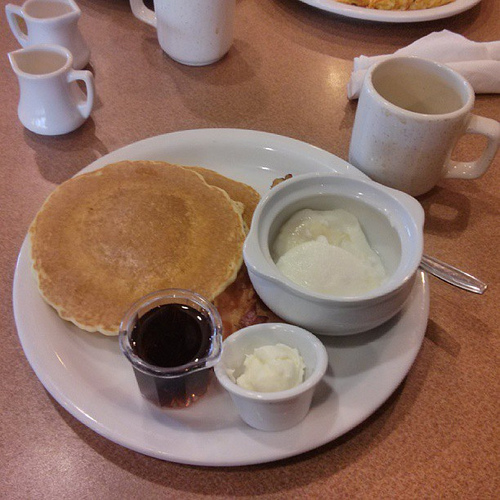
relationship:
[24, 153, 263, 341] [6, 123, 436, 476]
pancake on plate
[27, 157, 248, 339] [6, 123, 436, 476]
pancake lying on top of plate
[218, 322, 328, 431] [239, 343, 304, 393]
container with butter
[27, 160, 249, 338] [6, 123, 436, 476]
pancake on plate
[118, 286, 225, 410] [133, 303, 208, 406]
container for syrup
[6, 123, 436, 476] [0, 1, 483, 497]
plate on table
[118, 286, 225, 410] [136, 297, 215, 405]
container of syrup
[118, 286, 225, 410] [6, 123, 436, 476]
container on plate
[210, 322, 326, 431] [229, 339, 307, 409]
container of butter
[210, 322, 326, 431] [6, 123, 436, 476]
container on plate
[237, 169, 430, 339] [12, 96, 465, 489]
bowl on top of plate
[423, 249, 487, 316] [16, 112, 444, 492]
silverware on top of plate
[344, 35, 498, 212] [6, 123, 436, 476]
coffee mug next to plate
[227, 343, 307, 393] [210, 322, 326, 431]
butter in a container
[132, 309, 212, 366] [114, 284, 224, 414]
syrup in a cup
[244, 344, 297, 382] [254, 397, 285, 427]
butter in a bowl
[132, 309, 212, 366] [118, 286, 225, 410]
syrup in a container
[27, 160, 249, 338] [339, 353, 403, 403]
pancake are on a plate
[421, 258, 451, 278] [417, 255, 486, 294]
handle on a silverware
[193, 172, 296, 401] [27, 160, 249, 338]
bacon next to pancake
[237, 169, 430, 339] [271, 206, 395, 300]
bowl with butter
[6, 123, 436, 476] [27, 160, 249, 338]
plate with pancake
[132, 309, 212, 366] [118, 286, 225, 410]
syrup in container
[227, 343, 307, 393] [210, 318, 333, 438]
butter in container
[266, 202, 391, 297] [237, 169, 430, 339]
grits in bowl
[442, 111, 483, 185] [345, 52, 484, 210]
handle of coffee cup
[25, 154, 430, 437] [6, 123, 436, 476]
breakfast on plate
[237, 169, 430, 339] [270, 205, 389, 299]
bowl has egg whites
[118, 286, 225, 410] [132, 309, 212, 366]
container of syrup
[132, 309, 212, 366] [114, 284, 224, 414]
syrup in cup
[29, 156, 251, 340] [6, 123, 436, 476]
food on plate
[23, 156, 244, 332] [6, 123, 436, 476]
food on plate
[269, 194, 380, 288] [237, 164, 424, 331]
food on bowl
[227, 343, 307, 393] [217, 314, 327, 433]
butter in cup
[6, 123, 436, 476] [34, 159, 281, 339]
plate under food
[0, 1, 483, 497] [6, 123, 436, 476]
table under plate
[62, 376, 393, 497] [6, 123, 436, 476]
shadow from plate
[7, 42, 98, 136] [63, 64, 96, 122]
cup has handle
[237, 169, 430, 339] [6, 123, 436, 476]
bowl on plate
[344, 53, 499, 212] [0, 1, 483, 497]
coffee mug on table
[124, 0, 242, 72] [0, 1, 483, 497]
coffe cup on table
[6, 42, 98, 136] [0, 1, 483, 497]
cup on table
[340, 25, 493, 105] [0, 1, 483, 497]
napkin on table